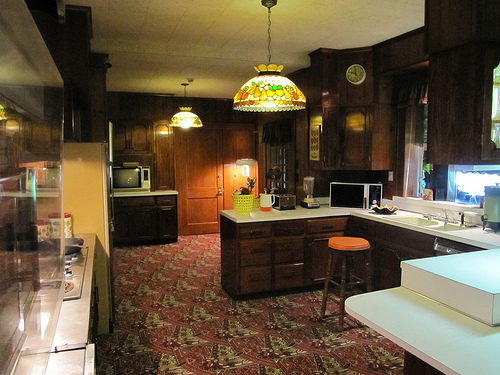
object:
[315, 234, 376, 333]
stool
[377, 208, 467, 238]
sink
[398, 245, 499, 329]
box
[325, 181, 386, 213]
microwave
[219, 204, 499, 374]
counter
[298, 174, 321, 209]
blender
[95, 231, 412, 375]
carpet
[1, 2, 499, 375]
kitchen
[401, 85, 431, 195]
window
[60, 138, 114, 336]
refrigerator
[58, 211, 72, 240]
cannister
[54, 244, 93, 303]
stove top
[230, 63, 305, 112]
ceiling light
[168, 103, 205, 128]
ceiling light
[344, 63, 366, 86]
clock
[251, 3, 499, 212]
wall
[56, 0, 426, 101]
ceiling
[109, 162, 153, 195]
tv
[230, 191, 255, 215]
basket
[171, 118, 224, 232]
door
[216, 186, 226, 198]
handle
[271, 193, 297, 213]
toaster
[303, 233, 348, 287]
cabinet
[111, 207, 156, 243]
cabinet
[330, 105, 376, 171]
cabinet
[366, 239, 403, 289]
cabinet